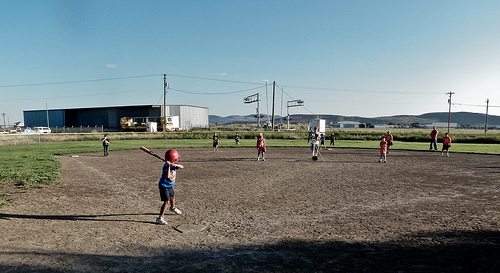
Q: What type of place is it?
A: It is a field.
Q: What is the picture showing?
A: It is showing a field.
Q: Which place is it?
A: It is a field.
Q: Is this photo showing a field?
A: Yes, it is showing a field.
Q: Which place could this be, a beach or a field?
A: It is a field.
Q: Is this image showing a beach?
A: No, the picture is showing a field.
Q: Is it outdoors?
A: Yes, it is outdoors.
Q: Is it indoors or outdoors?
A: It is outdoors.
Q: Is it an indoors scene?
A: No, it is outdoors.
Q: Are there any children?
A: Yes, there is a child.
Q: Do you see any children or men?
A: Yes, there is a child.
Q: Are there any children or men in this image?
A: Yes, there is a child.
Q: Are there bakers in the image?
A: No, there are no bakers.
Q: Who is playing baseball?
A: The kid is playing baseball.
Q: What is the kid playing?
A: The kid is playing baseball.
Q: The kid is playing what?
A: The kid is playing baseball.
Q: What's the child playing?
A: The kid is playing baseball.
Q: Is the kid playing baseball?
A: Yes, the kid is playing baseball.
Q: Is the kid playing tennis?
A: No, the kid is playing baseball.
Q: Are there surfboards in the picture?
A: No, there are no surfboards.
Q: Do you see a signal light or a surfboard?
A: No, there are no surfboards or traffic lights.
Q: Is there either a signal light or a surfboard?
A: No, there are no surfboards or traffic lights.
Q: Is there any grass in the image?
A: Yes, there is grass.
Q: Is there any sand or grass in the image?
A: Yes, there is grass.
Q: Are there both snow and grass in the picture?
A: No, there is grass but no snow.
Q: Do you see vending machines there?
A: No, there are no vending machines.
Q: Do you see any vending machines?
A: No, there are no vending machines.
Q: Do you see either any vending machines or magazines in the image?
A: No, there are no vending machines or magazines.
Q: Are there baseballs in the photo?
A: Yes, there is a baseball.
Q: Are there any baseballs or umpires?
A: Yes, there is a baseball.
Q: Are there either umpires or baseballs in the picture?
A: Yes, there is a baseball.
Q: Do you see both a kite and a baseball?
A: No, there is a baseball but no kites.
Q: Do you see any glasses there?
A: No, there are no glasses.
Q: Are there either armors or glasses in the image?
A: No, there are no glasses or armors.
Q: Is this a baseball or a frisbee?
A: This is a baseball.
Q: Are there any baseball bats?
A: Yes, there is a baseball bat.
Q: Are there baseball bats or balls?
A: Yes, there is a baseball bat.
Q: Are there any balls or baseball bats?
A: Yes, there is a baseball bat.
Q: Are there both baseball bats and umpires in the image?
A: No, there is a baseball bat but no umpires.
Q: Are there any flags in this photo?
A: No, there are no flags.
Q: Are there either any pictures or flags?
A: No, there are no flags or pictures.